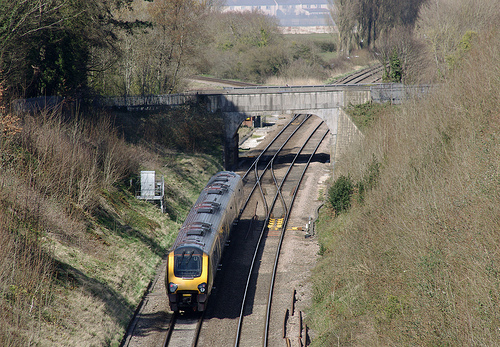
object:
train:
[164, 170, 246, 315]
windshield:
[174, 256, 201, 277]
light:
[198, 283, 207, 293]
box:
[140, 171, 155, 197]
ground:
[0, 33, 499, 346]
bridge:
[91, 83, 437, 169]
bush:
[328, 174, 350, 213]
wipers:
[178, 250, 195, 266]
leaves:
[109, 17, 156, 34]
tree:
[0, 1, 156, 98]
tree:
[166, 0, 207, 94]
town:
[224, 0, 344, 33]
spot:
[267, 217, 283, 229]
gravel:
[118, 58, 399, 347]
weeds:
[0, 113, 203, 345]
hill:
[308, 0, 500, 346]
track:
[216, 66, 398, 347]